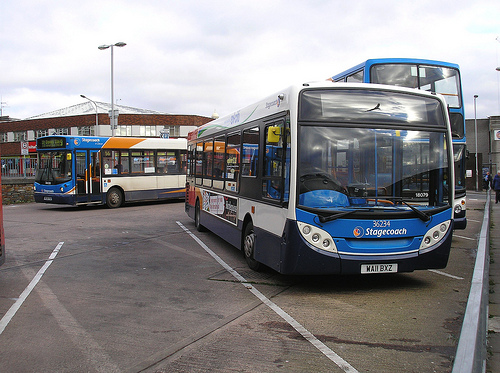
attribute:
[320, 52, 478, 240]
bus — double decker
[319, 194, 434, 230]
wiper — black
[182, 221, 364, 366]
line — white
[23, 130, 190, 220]
bus — orange  , blue white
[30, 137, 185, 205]
bus — Blue, Orange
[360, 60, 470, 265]
bus — double decker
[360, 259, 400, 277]
license plate — white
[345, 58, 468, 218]
bus — two story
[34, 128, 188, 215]
bus — blue, orange,, white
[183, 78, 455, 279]
bus — White , double decker, blue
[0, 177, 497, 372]
parking lot — white, striped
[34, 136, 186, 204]
buses — parked